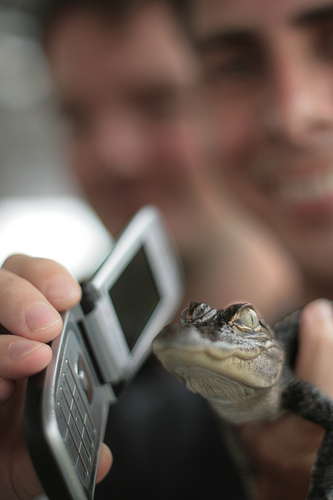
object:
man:
[0, 0, 333, 500]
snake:
[150, 298, 333, 500]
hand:
[233, 296, 333, 476]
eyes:
[180, 301, 211, 322]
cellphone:
[21, 202, 187, 500]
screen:
[108, 241, 161, 353]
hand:
[0, 252, 114, 500]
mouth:
[151, 335, 282, 390]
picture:
[0, 0, 333, 499]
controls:
[78, 368, 90, 390]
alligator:
[151, 299, 333, 500]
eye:
[231, 303, 262, 333]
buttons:
[61, 358, 77, 396]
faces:
[185, 0, 333, 278]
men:
[28, 5, 300, 500]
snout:
[151, 322, 202, 357]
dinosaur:
[150, 299, 333, 500]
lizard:
[150, 299, 333, 500]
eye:
[126, 85, 173, 111]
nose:
[91, 107, 151, 183]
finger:
[1, 251, 83, 312]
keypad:
[53, 331, 102, 495]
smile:
[250, 149, 333, 223]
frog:
[150, 299, 333, 500]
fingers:
[0, 251, 85, 403]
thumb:
[94, 438, 114, 485]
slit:
[249, 314, 253, 326]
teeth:
[275, 168, 333, 202]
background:
[0, 0, 333, 290]